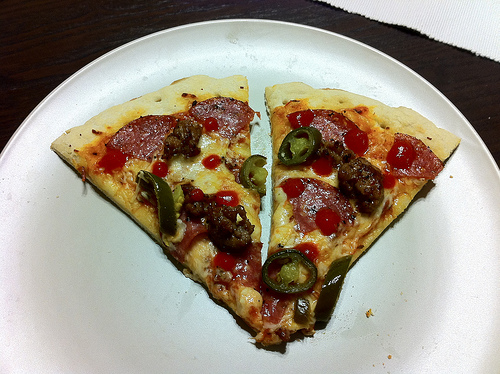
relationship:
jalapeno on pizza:
[131, 173, 179, 235] [90, 70, 461, 347]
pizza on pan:
[90, 70, 461, 347] [22, 19, 484, 353]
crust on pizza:
[64, 77, 245, 131] [90, 70, 461, 347]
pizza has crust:
[90, 70, 461, 347] [64, 77, 245, 131]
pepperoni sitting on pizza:
[285, 188, 345, 229] [264, 87, 455, 347]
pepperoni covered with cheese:
[285, 188, 345, 229] [198, 165, 223, 189]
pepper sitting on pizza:
[277, 117, 319, 162] [67, 80, 256, 340]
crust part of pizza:
[64, 77, 245, 131] [264, 87, 455, 347]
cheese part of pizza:
[195, 170, 230, 192] [90, 70, 461, 347]